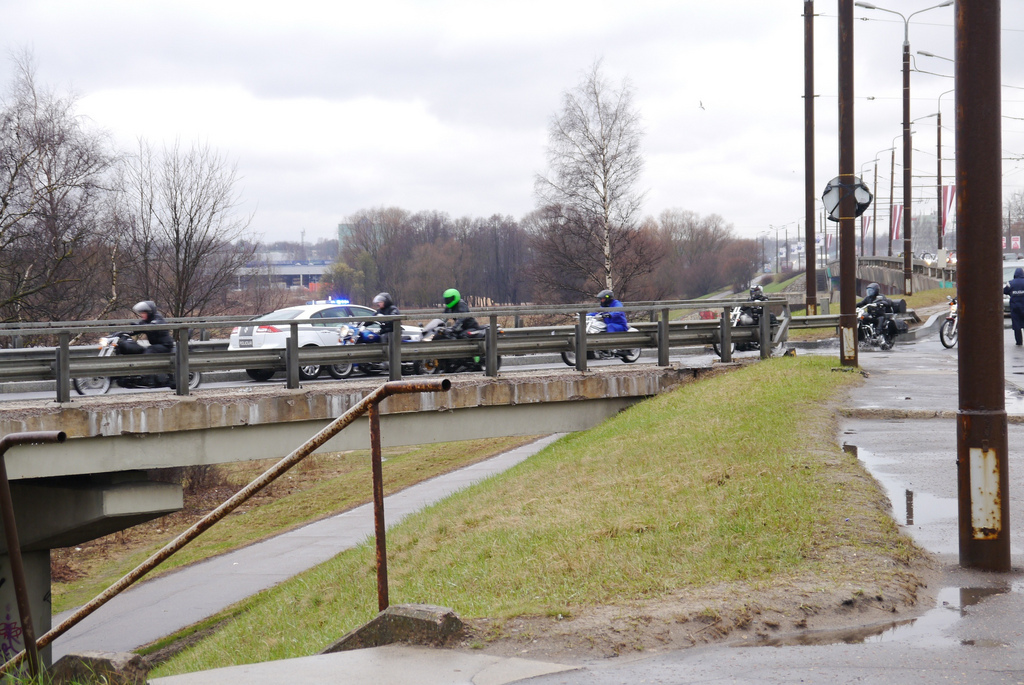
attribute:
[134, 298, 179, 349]
person — sitting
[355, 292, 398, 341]
person — sitting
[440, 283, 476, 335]
person — sitting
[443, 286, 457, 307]
helmet — green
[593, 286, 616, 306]
helmet — black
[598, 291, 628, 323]
jacket — blue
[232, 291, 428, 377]
car — white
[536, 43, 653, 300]
tree — tall, bare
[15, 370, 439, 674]
handrail — rusty , metal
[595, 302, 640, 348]
jacket — blue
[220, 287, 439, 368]
car — white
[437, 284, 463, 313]
helmet — green